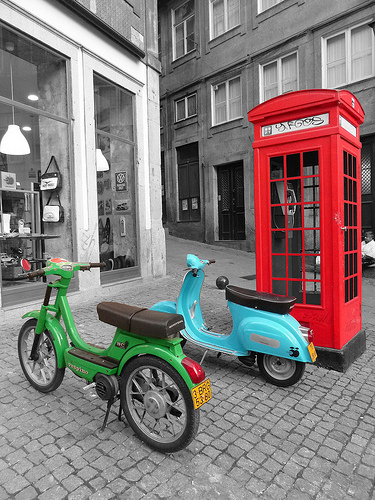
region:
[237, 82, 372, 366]
A red phone booth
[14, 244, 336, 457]
Two scooters are parked here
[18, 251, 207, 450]
This scooter is green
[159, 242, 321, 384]
This scooter is blue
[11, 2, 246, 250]
The background is in black and white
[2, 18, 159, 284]
This is a store front.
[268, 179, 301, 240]
A pay phone is inside the booth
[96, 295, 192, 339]
The scooter's seat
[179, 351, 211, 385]
The scooter's tail light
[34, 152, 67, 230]
Handbags are hanging in the store window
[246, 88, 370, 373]
red telephone booth on the street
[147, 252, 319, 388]
blue motorcycle on the street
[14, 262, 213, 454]
green motorcycle on the street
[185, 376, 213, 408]
yellow license plate on green motorcycle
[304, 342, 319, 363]
yellow license plate on the blue motorcycle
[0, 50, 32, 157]
white light hanging inside of the store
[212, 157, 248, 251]
black double door on the building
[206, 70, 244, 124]
white window on the building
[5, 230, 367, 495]
gray brick street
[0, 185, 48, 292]
shelf in the store window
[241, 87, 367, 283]
Red telephone booth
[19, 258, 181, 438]
Green scooter on cobble street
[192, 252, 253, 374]
Blue scooter on cobble street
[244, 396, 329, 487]
Small cobble stones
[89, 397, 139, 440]
Black kickstand on scooter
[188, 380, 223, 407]
Yellow license plate on back of scooter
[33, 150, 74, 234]
Bags in window display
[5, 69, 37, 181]
Storefront lighting fixtures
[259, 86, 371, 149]
Graffiti written on phone booth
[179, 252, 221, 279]
Scooter has black handle bars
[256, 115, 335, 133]
grafitti on red phone booth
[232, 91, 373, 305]
red telephone booth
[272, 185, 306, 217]
telephone inside red phone booth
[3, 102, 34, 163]
hanging lamp in store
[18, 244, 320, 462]
two unoccupied motor scooters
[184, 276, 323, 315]
rider's seat on turquoise motor scooter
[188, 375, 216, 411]
license plate on green scooter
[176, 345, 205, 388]
tail light on green motor scooter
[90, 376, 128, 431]
black kickstand on motor scooter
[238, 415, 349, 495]
grey pavement stones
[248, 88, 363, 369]
old fashioned red telephone booth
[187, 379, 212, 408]
rear scooter license plate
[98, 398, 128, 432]
motor scooter kick stand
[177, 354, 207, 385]
rear motor scooter brake light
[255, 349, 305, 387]
rear motor scooter wheel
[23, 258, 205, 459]
green two wheeled motor scooter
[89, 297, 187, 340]
black motor scooter seat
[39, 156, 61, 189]
purse hanging on a wall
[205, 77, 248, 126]
second story double window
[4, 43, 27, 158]
hanging pendant light